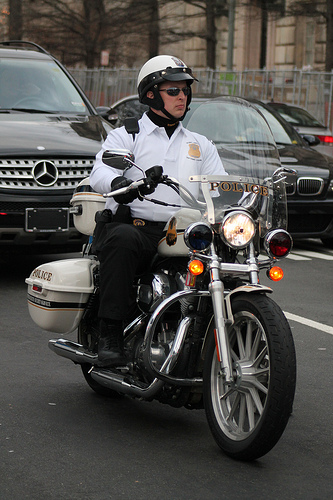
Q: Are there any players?
A: No, there are no players.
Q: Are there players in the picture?
A: No, there are no players.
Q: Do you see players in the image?
A: No, there are no players.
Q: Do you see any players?
A: No, there are no players.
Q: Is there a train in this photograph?
A: No, there are no trains.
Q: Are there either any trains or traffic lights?
A: No, there are no trains or traffic lights.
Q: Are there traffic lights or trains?
A: No, there are no trains or traffic lights.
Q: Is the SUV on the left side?
A: Yes, the SUV is on the left of the image.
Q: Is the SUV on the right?
A: No, the SUV is on the left of the image.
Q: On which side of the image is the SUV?
A: The SUV is on the left of the image.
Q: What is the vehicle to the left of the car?
A: The vehicle is a SUV.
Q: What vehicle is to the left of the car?
A: The vehicle is a SUV.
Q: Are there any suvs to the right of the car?
A: No, the SUV is to the left of the car.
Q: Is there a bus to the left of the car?
A: No, there is a SUV to the left of the car.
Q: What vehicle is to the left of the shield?
A: The vehicle is a SUV.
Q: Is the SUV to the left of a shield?
A: Yes, the SUV is to the left of a shield.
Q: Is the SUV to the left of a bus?
A: No, the SUV is to the left of a shield.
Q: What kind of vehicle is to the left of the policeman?
A: The vehicle is a SUV.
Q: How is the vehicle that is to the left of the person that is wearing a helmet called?
A: The vehicle is a SUV.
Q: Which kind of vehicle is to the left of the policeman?
A: The vehicle is a SUV.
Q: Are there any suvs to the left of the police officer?
A: Yes, there is a SUV to the left of the police officer.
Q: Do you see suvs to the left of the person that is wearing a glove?
A: Yes, there is a SUV to the left of the police officer.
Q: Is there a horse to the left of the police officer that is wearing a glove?
A: No, there is a SUV to the left of the policeman.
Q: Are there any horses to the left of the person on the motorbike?
A: No, there is a SUV to the left of the policeman.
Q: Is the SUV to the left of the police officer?
A: Yes, the SUV is to the left of the police officer.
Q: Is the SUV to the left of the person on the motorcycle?
A: Yes, the SUV is to the left of the police officer.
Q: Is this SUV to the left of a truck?
A: No, the SUV is to the left of the police officer.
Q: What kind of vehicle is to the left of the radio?
A: The vehicle is a SUV.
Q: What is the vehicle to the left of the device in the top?
A: The vehicle is a SUV.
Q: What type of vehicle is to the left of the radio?
A: The vehicle is a SUV.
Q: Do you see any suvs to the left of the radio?
A: Yes, there is a SUV to the left of the radio.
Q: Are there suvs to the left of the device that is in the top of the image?
A: Yes, there is a SUV to the left of the radio.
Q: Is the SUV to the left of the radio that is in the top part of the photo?
A: Yes, the SUV is to the left of the radio.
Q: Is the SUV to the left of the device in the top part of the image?
A: Yes, the SUV is to the left of the radio.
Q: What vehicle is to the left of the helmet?
A: The vehicle is a SUV.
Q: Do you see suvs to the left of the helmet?
A: Yes, there is a SUV to the left of the helmet.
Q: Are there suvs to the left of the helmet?
A: Yes, there is a SUV to the left of the helmet.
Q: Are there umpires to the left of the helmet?
A: No, there is a SUV to the left of the helmet.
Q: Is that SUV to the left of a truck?
A: No, the SUV is to the left of the helmet.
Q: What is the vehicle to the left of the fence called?
A: The vehicle is a SUV.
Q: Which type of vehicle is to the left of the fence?
A: The vehicle is a SUV.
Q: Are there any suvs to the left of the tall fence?
A: Yes, there is a SUV to the left of the fence.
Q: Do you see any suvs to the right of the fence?
A: No, the SUV is to the left of the fence.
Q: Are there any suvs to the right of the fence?
A: No, the SUV is to the left of the fence.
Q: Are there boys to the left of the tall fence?
A: No, there is a SUV to the left of the fence.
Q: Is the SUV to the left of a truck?
A: No, the SUV is to the left of a fence.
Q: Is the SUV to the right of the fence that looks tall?
A: No, the SUV is to the left of the fence.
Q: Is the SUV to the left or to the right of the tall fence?
A: The SUV is to the left of the fence.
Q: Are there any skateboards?
A: No, there are no skateboards.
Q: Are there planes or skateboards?
A: No, there are no skateboards or planes.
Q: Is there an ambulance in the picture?
A: No, there are no ambulances.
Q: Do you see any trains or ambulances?
A: No, there are no ambulances or trains.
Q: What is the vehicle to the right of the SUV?
A: The vehicle is a car.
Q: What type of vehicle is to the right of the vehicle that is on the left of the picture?
A: The vehicle is a car.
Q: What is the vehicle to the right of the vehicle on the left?
A: The vehicle is a car.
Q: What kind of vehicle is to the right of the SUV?
A: The vehicle is a car.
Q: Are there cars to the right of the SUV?
A: Yes, there is a car to the right of the SUV.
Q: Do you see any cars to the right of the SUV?
A: Yes, there is a car to the right of the SUV.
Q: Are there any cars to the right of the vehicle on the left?
A: Yes, there is a car to the right of the SUV.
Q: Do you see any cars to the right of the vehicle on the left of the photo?
A: Yes, there is a car to the right of the SUV.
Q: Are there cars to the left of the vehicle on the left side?
A: No, the car is to the right of the SUV.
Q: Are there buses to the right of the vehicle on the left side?
A: No, there is a car to the right of the SUV.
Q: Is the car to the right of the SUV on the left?
A: Yes, the car is to the right of the SUV.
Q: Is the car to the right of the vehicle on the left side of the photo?
A: Yes, the car is to the right of the SUV.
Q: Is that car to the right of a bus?
A: No, the car is to the right of the SUV.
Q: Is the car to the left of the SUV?
A: No, the car is to the right of the SUV.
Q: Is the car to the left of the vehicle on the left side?
A: No, the car is to the right of the SUV.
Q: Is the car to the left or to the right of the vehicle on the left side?
A: The car is to the right of the SUV.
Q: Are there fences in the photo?
A: Yes, there is a fence.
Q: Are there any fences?
A: Yes, there is a fence.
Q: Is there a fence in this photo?
A: Yes, there is a fence.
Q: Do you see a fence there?
A: Yes, there is a fence.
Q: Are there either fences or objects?
A: Yes, there is a fence.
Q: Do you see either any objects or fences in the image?
A: Yes, there is a fence.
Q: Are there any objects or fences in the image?
A: Yes, there is a fence.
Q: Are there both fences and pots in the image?
A: No, there is a fence but no pots.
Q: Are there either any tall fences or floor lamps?
A: Yes, there is a tall fence.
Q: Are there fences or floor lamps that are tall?
A: Yes, the fence is tall.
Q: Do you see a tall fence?
A: Yes, there is a tall fence.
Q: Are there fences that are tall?
A: Yes, there is a fence that is tall.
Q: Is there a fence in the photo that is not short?
A: Yes, there is a tall fence.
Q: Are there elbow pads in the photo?
A: No, there are no elbow pads.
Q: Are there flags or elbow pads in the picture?
A: No, there are no elbow pads or flags.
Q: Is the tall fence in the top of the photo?
A: Yes, the fence is in the top of the image.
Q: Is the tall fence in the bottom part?
A: No, the fence is in the top of the image.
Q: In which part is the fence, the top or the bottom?
A: The fence is in the top of the image.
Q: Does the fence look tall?
A: Yes, the fence is tall.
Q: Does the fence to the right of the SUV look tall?
A: Yes, the fence is tall.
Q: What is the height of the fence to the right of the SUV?
A: The fence is tall.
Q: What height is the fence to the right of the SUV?
A: The fence is tall.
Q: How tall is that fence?
A: The fence is tall.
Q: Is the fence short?
A: No, the fence is tall.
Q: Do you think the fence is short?
A: No, the fence is tall.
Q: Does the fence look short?
A: No, the fence is tall.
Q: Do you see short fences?
A: No, there is a fence but it is tall.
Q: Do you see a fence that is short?
A: No, there is a fence but it is tall.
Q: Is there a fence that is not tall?
A: No, there is a fence but it is tall.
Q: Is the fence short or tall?
A: The fence is tall.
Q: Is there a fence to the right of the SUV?
A: Yes, there is a fence to the right of the SUV.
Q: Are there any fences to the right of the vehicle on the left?
A: Yes, there is a fence to the right of the SUV.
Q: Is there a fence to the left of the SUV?
A: No, the fence is to the right of the SUV.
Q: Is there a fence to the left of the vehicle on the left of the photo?
A: No, the fence is to the right of the SUV.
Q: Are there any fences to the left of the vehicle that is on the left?
A: No, the fence is to the right of the SUV.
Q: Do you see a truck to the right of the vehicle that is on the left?
A: No, there is a fence to the right of the SUV.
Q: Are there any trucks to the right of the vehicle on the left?
A: No, there is a fence to the right of the SUV.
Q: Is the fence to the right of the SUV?
A: Yes, the fence is to the right of the SUV.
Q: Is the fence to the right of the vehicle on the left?
A: Yes, the fence is to the right of the SUV.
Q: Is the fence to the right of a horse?
A: No, the fence is to the right of the SUV.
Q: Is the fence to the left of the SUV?
A: No, the fence is to the right of the SUV.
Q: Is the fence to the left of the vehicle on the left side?
A: No, the fence is to the right of the SUV.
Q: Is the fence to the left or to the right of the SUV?
A: The fence is to the right of the SUV.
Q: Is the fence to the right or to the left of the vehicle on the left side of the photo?
A: The fence is to the right of the SUV.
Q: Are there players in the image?
A: No, there are no players.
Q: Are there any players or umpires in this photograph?
A: No, there are no players or umpires.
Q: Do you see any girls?
A: No, there are no girls.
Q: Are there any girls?
A: No, there are no girls.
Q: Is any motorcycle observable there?
A: Yes, there is a motorcycle.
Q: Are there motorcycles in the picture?
A: Yes, there is a motorcycle.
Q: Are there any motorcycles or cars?
A: Yes, there is a motorcycle.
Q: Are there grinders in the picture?
A: No, there are no grinders.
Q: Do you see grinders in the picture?
A: No, there are no grinders.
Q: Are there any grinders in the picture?
A: No, there are no grinders.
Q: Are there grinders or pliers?
A: No, there are no grinders or pliers.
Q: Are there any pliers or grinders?
A: No, there are no grinders or pliers.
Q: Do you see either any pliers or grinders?
A: No, there are no grinders or pliers.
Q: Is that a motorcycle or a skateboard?
A: That is a motorcycle.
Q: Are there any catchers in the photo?
A: No, there are no catchers.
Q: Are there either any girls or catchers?
A: No, there are no catchers or girls.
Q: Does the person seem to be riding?
A: Yes, the policeman is riding.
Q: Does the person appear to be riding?
A: Yes, the police officer is riding.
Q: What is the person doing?
A: The police officer is riding.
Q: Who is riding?
A: The policeman is riding.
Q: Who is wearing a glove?
A: The police officer is wearing a glove.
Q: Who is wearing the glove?
A: The police officer is wearing a glove.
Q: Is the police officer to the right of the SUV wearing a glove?
A: Yes, the policeman is wearing a glove.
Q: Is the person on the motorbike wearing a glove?
A: Yes, the policeman is wearing a glove.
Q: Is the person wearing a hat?
A: No, the police officer is wearing a glove.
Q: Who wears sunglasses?
A: The policeman wears sunglasses.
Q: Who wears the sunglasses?
A: The policeman wears sunglasses.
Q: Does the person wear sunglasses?
A: Yes, the policeman wears sunglasses.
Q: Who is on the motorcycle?
A: The police officer is on the motorcycle.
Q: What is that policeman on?
A: The policeman is on the motorcycle.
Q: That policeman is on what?
A: The policeman is on the motorcycle.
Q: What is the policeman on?
A: The policeman is on the motorcycle.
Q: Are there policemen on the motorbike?
A: Yes, there is a policeman on the motorbike.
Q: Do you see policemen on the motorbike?
A: Yes, there is a policeman on the motorbike.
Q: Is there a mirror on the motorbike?
A: No, there is a policeman on the motorbike.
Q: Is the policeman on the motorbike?
A: Yes, the policeman is on the motorbike.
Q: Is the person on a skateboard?
A: No, the police officer is on the motorbike.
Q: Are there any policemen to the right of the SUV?
A: Yes, there is a policeman to the right of the SUV.